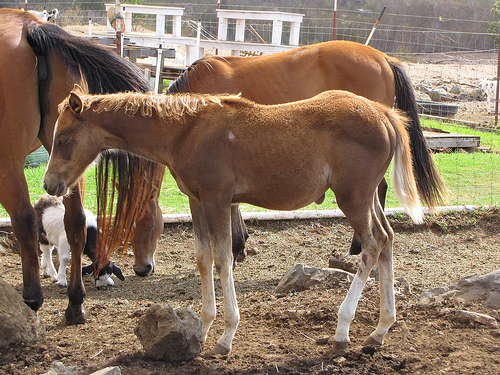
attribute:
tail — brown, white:
[384, 105, 426, 224]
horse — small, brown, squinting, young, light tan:
[43, 83, 426, 356]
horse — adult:
[2, 30, 164, 325]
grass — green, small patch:
[448, 158, 484, 182]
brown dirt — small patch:
[271, 313, 307, 329]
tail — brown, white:
[388, 105, 427, 225]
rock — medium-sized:
[132, 302, 202, 360]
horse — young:
[130, 35, 447, 276]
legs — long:
[330, 188, 411, 359]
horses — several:
[9, 17, 490, 372]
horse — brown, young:
[23, 76, 483, 371]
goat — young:
[26, 190, 128, 292]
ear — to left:
[64, 87, 90, 118]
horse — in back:
[22, 57, 499, 358]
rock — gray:
[130, 298, 207, 363]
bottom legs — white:
[186, 266, 397, 356]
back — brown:
[216, 94, 323, 117]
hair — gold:
[81, 88, 246, 116]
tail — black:
[410, 63, 447, 206]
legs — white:
[195, 241, 397, 352]